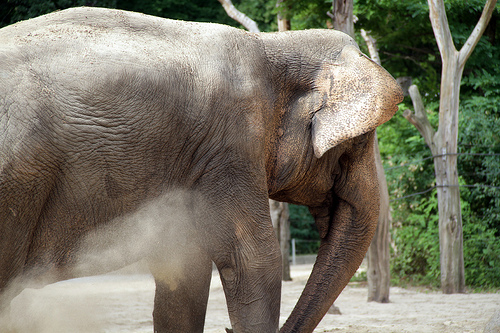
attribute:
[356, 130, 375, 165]
eye — black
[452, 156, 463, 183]
ground — gray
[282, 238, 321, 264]
fence — small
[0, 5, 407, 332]
elephant — asian, grey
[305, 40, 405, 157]
ear — floppy, gray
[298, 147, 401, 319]
trunk — gray, long, thick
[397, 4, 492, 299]
tree — smooth, bare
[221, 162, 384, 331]
trunk — bent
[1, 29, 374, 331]
wrinkled skin — gray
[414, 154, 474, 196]
rope — black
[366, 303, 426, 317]
dirt — gray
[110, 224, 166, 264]
cloud — dusty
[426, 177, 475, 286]
bush — green, thick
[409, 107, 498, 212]
bush — green, thick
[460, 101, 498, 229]
bush — green, thick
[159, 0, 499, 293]
leaves — green